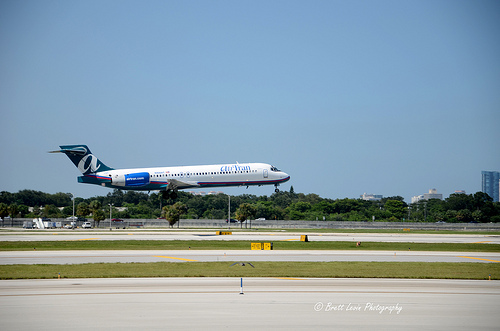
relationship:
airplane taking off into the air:
[46, 117, 292, 221] [11, 6, 490, 216]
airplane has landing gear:
[46, 117, 292, 221] [153, 184, 186, 210]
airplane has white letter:
[46, 117, 292, 221] [74, 149, 101, 180]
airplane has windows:
[46, 117, 292, 221] [97, 165, 264, 180]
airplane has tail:
[46, 117, 292, 221] [41, 132, 106, 192]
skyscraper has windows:
[478, 165, 499, 205] [482, 173, 495, 202]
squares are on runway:
[247, 237, 279, 265] [7, 221, 496, 265]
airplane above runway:
[46, 117, 292, 221] [7, 221, 496, 265]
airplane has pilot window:
[46, 117, 292, 221] [268, 160, 285, 182]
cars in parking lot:
[16, 211, 99, 233] [0, 214, 145, 228]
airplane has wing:
[46, 117, 292, 221] [158, 173, 211, 208]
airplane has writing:
[46, 117, 292, 221] [216, 160, 256, 177]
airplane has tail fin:
[46, 117, 292, 221] [51, 144, 82, 155]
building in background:
[423, 187, 445, 209] [287, 166, 493, 204]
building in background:
[362, 190, 383, 205] [287, 166, 493, 204]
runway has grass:
[7, 221, 496, 265] [3, 262, 499, 283]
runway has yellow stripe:
[7, 221, 496, 265] [154, 247, 195, 270]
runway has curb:
[7, 221, 496, 265] [0, 277, 494, 294]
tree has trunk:
[233, 200, 251, 233] [239, 222, 247, 232]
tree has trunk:
[160, 197, 191, 235] [167, 219, 178, 232]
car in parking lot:
[46, 217, 52, 227] [0, 214, 145, 228]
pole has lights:
[68, 190, 76, 227] [67, 193, 79, 203]